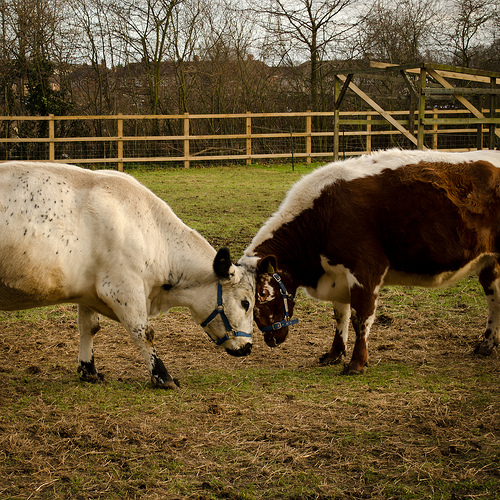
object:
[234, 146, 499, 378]
cow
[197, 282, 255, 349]
harness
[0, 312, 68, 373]
hay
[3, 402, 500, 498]
grass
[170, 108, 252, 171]
fence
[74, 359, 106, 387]
hooves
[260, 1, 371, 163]
trees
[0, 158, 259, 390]
cows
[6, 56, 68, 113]
buildings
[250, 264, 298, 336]
muzzle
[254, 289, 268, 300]
eye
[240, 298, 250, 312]
eye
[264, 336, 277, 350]
nose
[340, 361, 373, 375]
hoof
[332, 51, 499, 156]
structure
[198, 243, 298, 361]
heads together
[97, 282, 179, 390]
legs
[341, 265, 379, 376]
legs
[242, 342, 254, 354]
noses